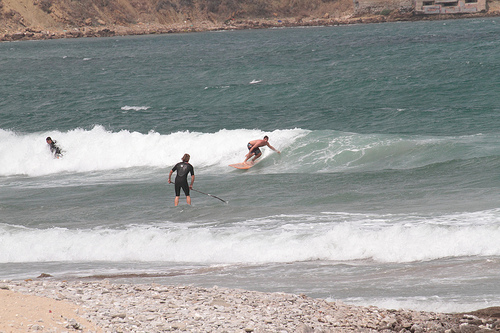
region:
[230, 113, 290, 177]
surfer on surfboard in water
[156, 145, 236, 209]
man in black wetsuit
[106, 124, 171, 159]
white waves crashing in ocean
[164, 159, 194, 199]
black wetsuit on person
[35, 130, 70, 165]
person in white waves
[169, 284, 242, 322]
rocks on beach shore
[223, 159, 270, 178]
orange surfboard in water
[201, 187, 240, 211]
oar in ocean water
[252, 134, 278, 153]
man without a shirt on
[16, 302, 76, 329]
beach with sand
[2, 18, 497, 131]
the water is blue.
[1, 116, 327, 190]
the waves are white.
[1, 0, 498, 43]
cliffs in the background.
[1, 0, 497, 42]
the cliffs are brown.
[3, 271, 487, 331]
rocks on the sand.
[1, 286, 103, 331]
the sand is tan.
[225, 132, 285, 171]
man standing on surfboard.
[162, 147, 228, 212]
the man is paddle boarding.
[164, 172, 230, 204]
man holding a paddle.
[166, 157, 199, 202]
the wetsuit is black.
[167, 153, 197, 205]
a person standing in the ocean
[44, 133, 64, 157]
a person standing in the ocean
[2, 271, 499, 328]
a rocky beach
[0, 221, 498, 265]
the white crest of a long wave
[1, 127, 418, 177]
the white crest of a long wave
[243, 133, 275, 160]
a man surfing without a shirt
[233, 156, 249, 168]
a tan surfboard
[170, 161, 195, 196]
a black short sleeved wet suit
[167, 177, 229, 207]
a long ore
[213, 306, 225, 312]
a rock on the beach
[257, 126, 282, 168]
Man has dark shirt.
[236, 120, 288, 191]
Man has dark shorts on.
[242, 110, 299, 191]
Man is not wearing shirt.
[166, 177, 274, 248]
Man holding paddle.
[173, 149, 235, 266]
Man wearing wet suit.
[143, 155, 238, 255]
Wet suit is black.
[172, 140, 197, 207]
Person has brown hair.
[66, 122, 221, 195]
Waves crashing in have white tops.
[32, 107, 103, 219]
Person engulfed in wave.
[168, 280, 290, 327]
Pebbles on shore.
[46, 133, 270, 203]
three people in the water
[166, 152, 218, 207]
a person is paddle boarding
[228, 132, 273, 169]
a person is surfing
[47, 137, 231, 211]
two people wear suits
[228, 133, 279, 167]
the man is wearing shorts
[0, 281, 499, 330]
the sand is rocky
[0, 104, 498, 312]
the ocean has waves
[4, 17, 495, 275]
the water is blue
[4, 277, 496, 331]
the sand is brown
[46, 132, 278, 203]
the men are on the waves